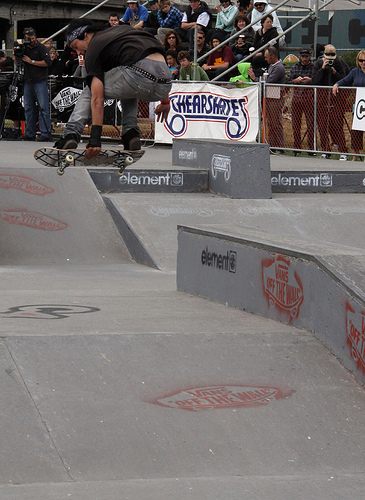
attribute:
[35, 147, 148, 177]
skateboard — black, white, present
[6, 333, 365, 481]
ramp — concrete, grey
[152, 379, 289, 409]
vans logo — present, red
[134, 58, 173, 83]
boxers — sticking out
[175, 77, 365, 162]
fence — metal, grey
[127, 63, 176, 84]
belt — black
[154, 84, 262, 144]
sign — red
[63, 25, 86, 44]
headband — blue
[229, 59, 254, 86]
jacket — green, bright green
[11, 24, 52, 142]
man — filming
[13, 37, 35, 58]
video camera — large, black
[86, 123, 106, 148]
wristband — black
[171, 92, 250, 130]
writing — blue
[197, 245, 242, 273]
element logo — black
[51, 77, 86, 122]
banner — black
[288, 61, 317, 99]
shirt — plaid, flannel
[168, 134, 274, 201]
wall — concrete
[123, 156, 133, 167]
wheel — white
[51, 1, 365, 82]
crowd — present, sitting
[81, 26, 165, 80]
shirt — black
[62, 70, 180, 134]
jeans — denim, blue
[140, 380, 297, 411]
graffiti — red